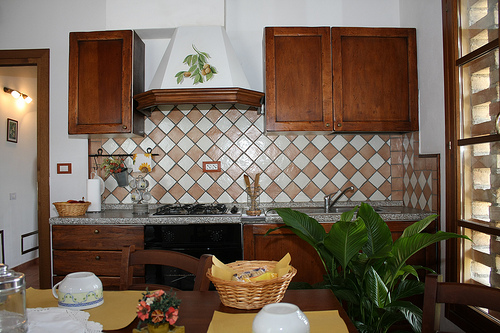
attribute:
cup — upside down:
[46, 268, 108, 314]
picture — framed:
[5, 115, 20, 145]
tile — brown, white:
[87, 101, 404, 202]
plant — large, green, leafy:
[266, 200, 475, 331]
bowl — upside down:
[246, 303, 306, 330]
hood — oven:
[141, 22, 271, 112]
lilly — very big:
[263, 193, 480, 331]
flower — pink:
[135, 300, 151, 322]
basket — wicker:
[51, 197, 92, 218]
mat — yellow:
[200, 295, 350, 330]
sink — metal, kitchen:
[288, 183, 402, 238]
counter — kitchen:
[44, 197, 434, 225]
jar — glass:
[0, 275, 47, 330]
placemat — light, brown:
[204, 305, 351, 332]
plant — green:
[287, 199, 432, 296]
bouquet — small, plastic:
[137, 287, 182, 329]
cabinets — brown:
[243, 23, 433, 153]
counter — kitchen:
[43, 196, 435, 232]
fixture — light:
[3, 82, 21, 106]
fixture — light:
[19, 89, 36, 111]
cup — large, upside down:
[46, 269, 110, 310]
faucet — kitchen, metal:
[323, 183, 354, 209]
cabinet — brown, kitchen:
[66, 29, 140, 139]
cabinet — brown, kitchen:
[258, 22, 334, 132]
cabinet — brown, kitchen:
[334, 23, 420, 139]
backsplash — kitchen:
[88, 102, 439, 212]